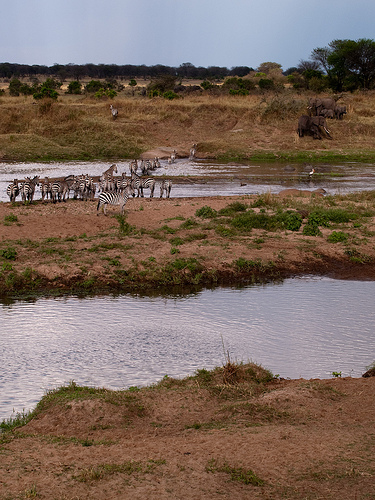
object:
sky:
[0, 1, 374, 72]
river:
[0, 156, 375, 206]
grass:
[2, 95, 374, 500]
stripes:
[7, 157, 172, 216]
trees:
[1, 38, 375, 98]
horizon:
[1, 34, 374, 74]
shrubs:
[196, 200, 355, 245]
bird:
[309, 169, 315, 177]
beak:
[313, 169, 314, 172]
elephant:
[298, 98, 347, 140]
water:
[0, 265, 373, 429]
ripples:
[1, 276, 375, 423]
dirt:
[2, 208, 195, 241]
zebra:
[7, 104, 198, 215]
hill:
[0, 101, 371, 161]